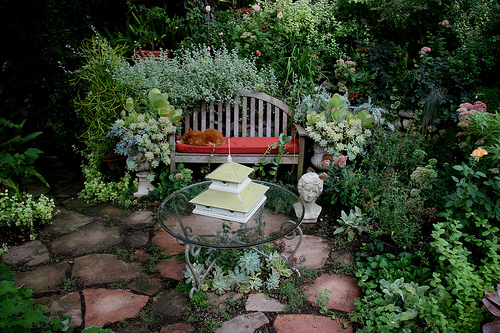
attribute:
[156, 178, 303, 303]
table — glass, low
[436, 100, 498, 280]
vegetation — green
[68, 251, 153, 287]
stone — flat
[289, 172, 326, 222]
bust — female bust, replica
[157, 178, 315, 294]
table — glass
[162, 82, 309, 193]
bench — wooden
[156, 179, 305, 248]
table — glass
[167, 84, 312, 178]
bench — wooden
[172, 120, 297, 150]
cushion — red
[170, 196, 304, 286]
legs — metal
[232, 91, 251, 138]
slat — wooden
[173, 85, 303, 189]
bench — wooden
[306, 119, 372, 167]
flowers — white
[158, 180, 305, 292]
table — glass